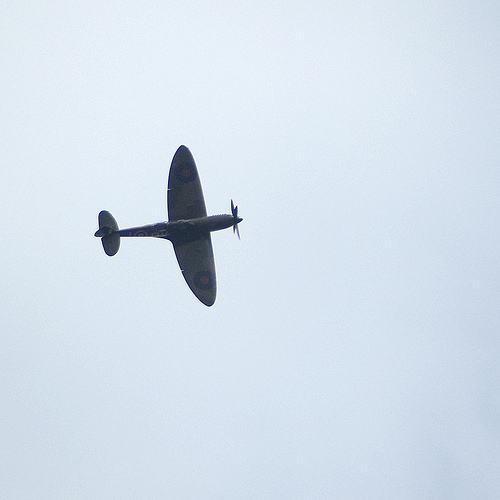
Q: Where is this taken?
A: In the sky.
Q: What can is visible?
A: The underside of a plane.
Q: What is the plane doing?
A: Flying.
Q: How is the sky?
A: Gray and blue.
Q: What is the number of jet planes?
A: One.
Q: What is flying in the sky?
A: A jet plane.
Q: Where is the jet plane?
A: In the sky.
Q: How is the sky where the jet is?
A: Light blue.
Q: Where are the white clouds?
A: In a blue sky.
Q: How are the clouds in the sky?
A: Blue.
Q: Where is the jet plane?
A: In the air.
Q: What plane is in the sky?
A: A jet.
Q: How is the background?
A: Blue sky.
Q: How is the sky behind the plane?
A: Blue.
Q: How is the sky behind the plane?
A: With no clouds.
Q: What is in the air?
A: A plane.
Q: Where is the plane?
A: In the sky.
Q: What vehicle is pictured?
A: An airplane.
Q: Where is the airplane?
A: In the sky.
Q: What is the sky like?
A: Clear.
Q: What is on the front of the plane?
A: A propeller.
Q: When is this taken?
A: Daytime.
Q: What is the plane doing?
A: Flying in the sky.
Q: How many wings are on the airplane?
A: Two.